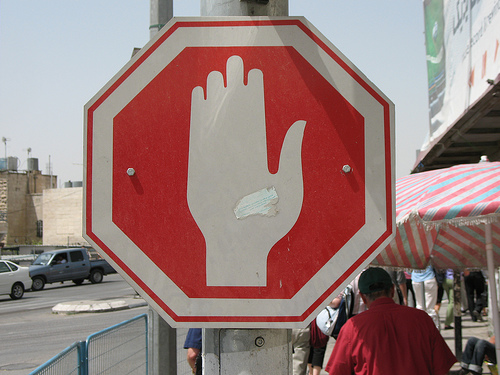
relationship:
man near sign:
[351, 259, 425, 343] [121, 68, 378, 298]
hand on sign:
[182, 74, 317, 239] [121, 68, 378, 298]